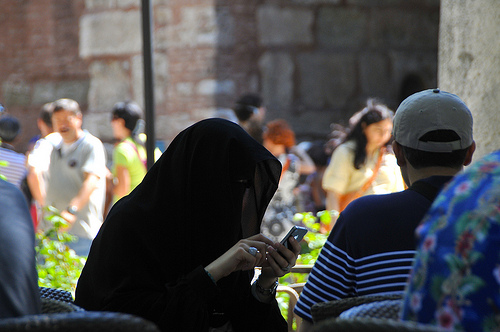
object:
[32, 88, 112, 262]
person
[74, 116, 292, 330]
clothing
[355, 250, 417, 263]
stripe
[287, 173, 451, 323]
shirt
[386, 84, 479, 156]
hat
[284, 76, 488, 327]
man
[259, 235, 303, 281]
hand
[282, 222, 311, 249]
cellphone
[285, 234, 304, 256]
finger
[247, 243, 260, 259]
ring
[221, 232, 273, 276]
hand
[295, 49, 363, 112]
stones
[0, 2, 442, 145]
wall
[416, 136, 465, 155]
strap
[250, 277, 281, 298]
watch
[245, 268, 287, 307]
wrist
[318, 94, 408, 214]
woman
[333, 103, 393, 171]
hair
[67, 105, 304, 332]
person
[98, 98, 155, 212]
man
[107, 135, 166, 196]
shirt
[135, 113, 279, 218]
head